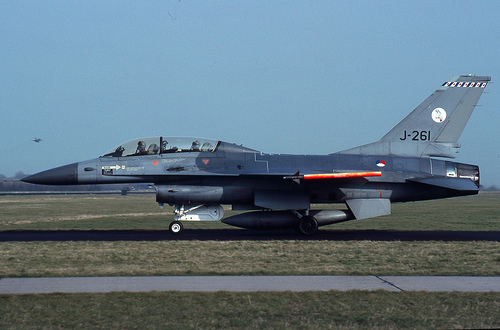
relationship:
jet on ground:
[122, 59, 484, 295] [0, 194, 498, 328]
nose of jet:
[3, 156, 80, 193] [20, 74, 488, 237]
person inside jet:
[130, 137, 147, 158] [20, 74, 488, 237]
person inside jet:
[184, 132, 203, 150] [20, 74, 488, 237]